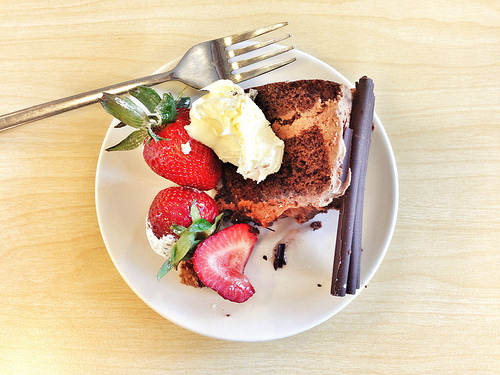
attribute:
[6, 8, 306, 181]
fork — gray, metal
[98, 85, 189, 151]
leaf — Green 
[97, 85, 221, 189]
strawberry — Red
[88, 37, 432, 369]
plate — white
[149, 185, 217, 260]
strawberry — Red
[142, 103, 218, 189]
strawberry — Red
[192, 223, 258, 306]
strawberry — Red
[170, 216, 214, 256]
green leaf — Green 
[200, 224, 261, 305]
strawberry — Red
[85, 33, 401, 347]
plate — white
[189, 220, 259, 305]
strawberry — sliced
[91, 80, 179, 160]
leaf — green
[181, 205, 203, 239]
green leaf — Green 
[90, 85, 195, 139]
green leaf — Green 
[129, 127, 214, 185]
strawberry — Red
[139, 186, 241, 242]
strawberry — Red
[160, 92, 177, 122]
leaf — Green 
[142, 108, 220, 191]
strawberry — Red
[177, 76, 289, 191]
cream — whipped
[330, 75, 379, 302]
stick — chocolate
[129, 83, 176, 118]
leaf — green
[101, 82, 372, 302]
foods — healthy